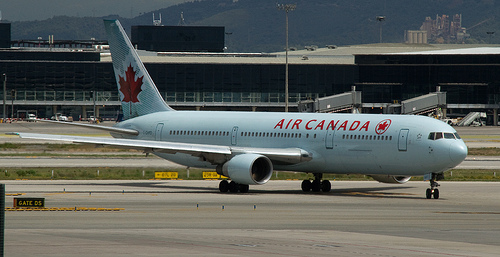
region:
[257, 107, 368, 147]
Air Canada on the plane.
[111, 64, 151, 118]
Maple leaf on the tail.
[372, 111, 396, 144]
Maple leaf in a circle.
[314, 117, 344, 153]
Door on the plane.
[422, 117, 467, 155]
Windshield on the plane.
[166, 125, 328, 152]
Windows on the plane.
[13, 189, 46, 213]
Small sign says "Gate DS".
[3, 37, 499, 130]
Airport terminal in the background.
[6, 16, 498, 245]
Taken at an airport.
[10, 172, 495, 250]
Plane on the tarmac.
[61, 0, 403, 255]
plane on the runway.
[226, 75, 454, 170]
Air Canada plane on the runway.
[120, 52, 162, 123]
Red leaf on the plane.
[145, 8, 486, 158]
Buildings in the background.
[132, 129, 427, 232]
Engine on the plane.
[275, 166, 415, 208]
Wheels on the plane.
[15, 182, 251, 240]
Sign on the road.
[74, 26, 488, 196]
Red maple leaf on the plane.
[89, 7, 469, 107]
Mountains in the background.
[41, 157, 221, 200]
Grass behind the plane.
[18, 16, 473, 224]
airplane on the tarmac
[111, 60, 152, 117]
red maple leaf on the tail of the plane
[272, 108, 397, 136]
large red air canada logo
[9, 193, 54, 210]
black and yellow gate sign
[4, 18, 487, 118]
terminal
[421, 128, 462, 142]
windosw of the cockpit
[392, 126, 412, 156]
door on the front of the plane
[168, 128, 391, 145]
long row of tiny windows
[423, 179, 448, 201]
front wheel is down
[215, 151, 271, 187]
jet engine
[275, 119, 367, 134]
The Air Canada brand name on plane.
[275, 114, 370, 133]
Red lettering on white plane.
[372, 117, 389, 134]
Air Canada logo on plane.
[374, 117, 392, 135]
Red leave inside a circle on plane.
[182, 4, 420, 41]
Mountain range in the background.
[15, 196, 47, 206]
The sign showing 'Gate D5' on runway.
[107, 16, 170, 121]
Tail of white plane with a red leaf.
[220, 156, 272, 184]
Side mounted engine on plane.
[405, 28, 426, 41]
White multi-leveled building in background.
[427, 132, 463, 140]
Cockpit window on front of plane.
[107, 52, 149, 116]
red maple leaf outlined in white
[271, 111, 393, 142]
Air Canada logo painted on plane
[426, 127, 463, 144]
windshield on front of plane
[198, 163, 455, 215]
plane wheels on the ground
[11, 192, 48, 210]
sign for gate D5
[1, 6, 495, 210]
airport terminal behind plane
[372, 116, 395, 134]
red maple leaf in circle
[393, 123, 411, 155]
passenger door on side of plane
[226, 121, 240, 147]
emergency door on side of plane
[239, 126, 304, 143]
small passenger windows